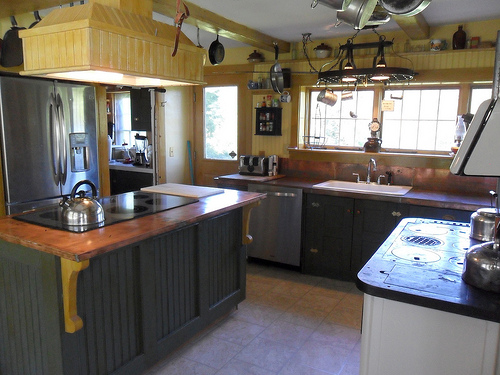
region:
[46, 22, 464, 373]
picture of kitchen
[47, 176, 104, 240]
silver and black tea kettle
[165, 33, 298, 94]
pans hanging from ceiling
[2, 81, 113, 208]
silver two door refrigerator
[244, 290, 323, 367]
tan tiled kitchen floor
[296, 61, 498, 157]
long row of kitchen windows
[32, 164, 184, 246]
stove top built into kitchen island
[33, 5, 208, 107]
vent for stove painted yellow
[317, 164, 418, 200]
white sink with brown counter top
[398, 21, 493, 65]
various items on shelf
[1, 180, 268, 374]
a kitchen island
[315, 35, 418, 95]
a black pot rack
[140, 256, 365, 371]
the floor is tiled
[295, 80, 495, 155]
three windows in wall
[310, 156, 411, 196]
a white kitchen sink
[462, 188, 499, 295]
two silver tea kettles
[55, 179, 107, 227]
one silver tea kettle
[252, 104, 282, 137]
a black spice rack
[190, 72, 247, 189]
a door with a window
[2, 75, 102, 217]
a silver refrigerator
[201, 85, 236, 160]
Window on a door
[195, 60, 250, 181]
Wooden door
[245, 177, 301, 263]
Silver dishwasher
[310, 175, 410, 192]
White sink on a counter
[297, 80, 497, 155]
Set of windows above a sink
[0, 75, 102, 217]
Silver refrigerator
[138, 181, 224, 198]
White cutting board sitting on a counter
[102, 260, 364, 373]
Tile floor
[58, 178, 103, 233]
Silver kettle on a stove on a wooden counter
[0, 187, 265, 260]
Wooden counter top with a stove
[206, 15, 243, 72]
Iron skillet hanging from ceiling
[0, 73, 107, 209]
Stainless steel double door fridge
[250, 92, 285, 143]
Black spice rack on wall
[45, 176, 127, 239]
Stainless steel tea kettle on stove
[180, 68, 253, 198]
Wooden door with window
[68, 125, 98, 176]
Ice maker on fridge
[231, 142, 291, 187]
Stainless steel four slice toaster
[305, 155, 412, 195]
White sink with silver faucet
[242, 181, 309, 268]
Stainless steel dishwasher next to sink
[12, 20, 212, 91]
Wood covered vent over stove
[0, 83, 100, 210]
stainless steel double door refrigerator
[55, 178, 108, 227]
chrome whistling tea kettle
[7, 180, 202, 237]
smooth electric cooktop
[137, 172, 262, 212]
cutting board on countertop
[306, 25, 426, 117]
hanging metal pot rack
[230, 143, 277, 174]
metal finish toaster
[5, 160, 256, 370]
large kitchen island with cooktop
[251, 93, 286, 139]
spice rack with jars on it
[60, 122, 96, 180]
in-door ice dispenser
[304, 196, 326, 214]
metal cabinet hinge